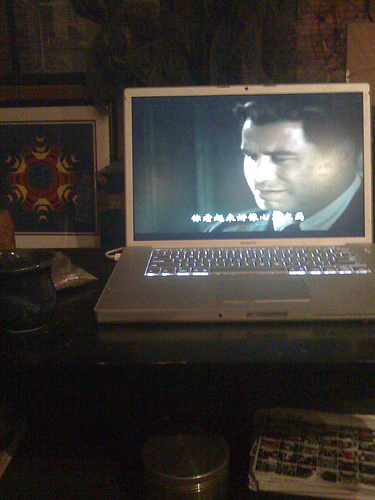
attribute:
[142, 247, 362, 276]
keyboard — backlit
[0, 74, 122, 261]
graphic print — framed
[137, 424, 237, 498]
disc case — small, round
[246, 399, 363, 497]
book — large, white, paper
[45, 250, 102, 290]
bag — small, plastic, clear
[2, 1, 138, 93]
picture painting — large, colored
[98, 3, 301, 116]
drapes — large, wide, green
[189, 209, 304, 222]
letters — asian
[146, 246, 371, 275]
keyboard — lit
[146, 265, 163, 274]
key — gray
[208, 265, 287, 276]
key — gray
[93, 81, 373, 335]
laptop — large, silver, small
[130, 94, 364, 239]
screen — on, large, square